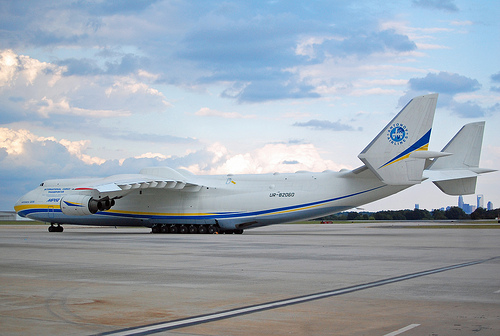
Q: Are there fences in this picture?
A: No, there are no fences.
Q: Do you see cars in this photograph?
A: No, there are no cars.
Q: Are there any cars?
A: No, there are no cars.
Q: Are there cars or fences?
A: No, there are no cars or fences.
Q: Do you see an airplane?
A: Yes, there is an airplane.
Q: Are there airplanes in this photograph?
A: Yes, there is an airplane.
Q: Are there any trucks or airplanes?
A: Yes, there is an airplane.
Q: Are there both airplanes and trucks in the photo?
A: No, there is an airplane but no trucks.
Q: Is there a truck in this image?
A: No, there are no trucks.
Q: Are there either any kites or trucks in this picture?
A: No, there are no trucks or kites.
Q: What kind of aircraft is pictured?
A: The aircraft is an airplane.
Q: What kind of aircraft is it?
A: The aircraft is an airplane.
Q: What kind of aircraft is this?
A: This is an airplane.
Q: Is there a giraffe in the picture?
A: No, there are no giraffes.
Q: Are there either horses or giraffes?
A: No, there are no giraffes or horses.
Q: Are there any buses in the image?
A: No, there are no buses.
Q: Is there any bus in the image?
A: No, there are no buses.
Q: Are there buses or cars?
A: No, there are no buses or cars.